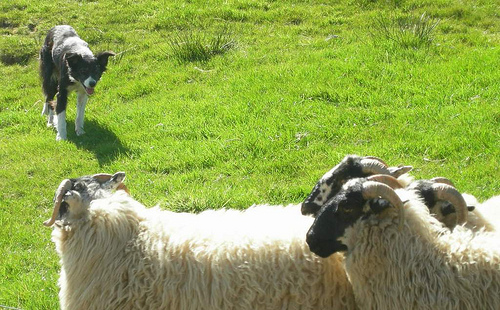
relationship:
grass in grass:
[157, 27, 243, 64] [153, 28, 437, 133]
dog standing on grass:
[34, 21, 118, 145] [1, 0, 498, 309]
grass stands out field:
[157, 19, 250, 87] [264, 36, 486, 139]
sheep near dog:
[43, 170, 359, 309] [13, 27, 113, 143]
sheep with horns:
[31, 147, 467, 307] [38, 176, 92, 221]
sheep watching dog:
[43, 170, 359, 309] [32, 18, 112, 143]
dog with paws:
[34, 21, 107, 139] [54, 125, 86, 144]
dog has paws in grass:
[34, 21, 118, 145] [224, 96, 304, 141]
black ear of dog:
[94, 50, 114, 61] [34, 21, 118, 145]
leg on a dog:
[73, 87, 89, 138] [34, 21, 107, 139]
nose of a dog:
[87, 78, 95, 87] [34, 21, 118, 145]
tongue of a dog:
[86, 87, 94, 94] [34, 21, 118, 145]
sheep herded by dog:
[43, 170, 359, 309] [27, 18, 117, 155]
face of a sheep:
[300, 179, 380, 256] [304, 172, 498, 300]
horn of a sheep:
[373, 193, 392, 214] [43, 170, 359, 309]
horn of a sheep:
[47, 177, 71, 226] [43, 170, 359, 309]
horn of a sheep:
[362, 155, 396, 176] [43, 170, 359, 309]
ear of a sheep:
[103, 171, 129, 188] [43, 170, 359, 309]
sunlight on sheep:
[92, 188, 313, 251] [43, 170, 359, 309]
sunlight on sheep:
[393, 165, 497, 257] [43, 170, 359, 309]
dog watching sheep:
[34, 21, 118, 145] [43, 170, 359, 309]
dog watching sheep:
[34, 21, 118, 145] [304, 172, 498, 300]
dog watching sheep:
[34, 21, 118, 145] [298, 149, 382, 214]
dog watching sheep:
[34, 21, 118, 145] [402, 168, 473, 228]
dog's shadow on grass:
[8, 124, 190, 182] [249, 75, 366, 143]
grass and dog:
[124, 5, 499, 159] [34, 21, 118, 145]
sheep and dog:
[43, 170, 359, 309] [34, 21, 118, 145]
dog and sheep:
[34, 21, 118, 145] [43, 170, 359, 309]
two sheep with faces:
[299, 153, 498, 308] [307, 173, 369, 266]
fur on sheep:
[41, 162, 498, 308] [58, 189, 385, 309]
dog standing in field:
[34, 21, 118, 145] [3, 5, 497, 300]